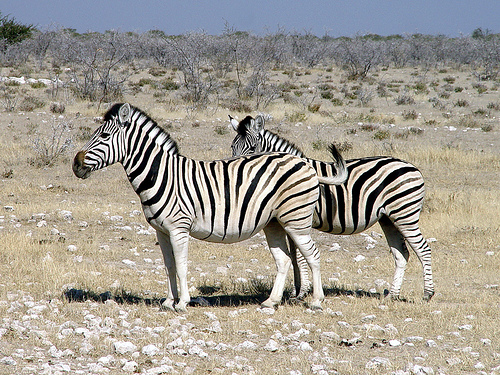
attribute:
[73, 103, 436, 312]
two zebras — standing on plain, striped, black, white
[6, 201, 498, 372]
small rocks — white, covering the ground, in front of zebras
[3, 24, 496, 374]
ground — rocky, full of dead grass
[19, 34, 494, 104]
bare trees — in background, dry in the back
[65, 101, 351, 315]
zebra — standing in field, black, white, covered in stripes, brown,& tan, wagging its tail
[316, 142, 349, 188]
tail with black tip — wagging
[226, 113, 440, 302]
zebra — showing two ears, hidden behind zebra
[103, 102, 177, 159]
mane — black, white